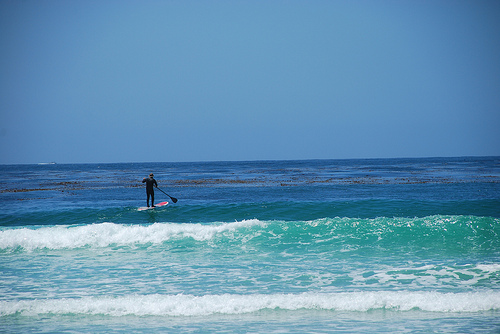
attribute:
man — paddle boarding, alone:
[141, 173, 157, 208]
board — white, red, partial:
[139, 198, 172, 218]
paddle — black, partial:
[152, 184, 181, 205]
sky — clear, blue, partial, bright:
[1, 1, 500, 163]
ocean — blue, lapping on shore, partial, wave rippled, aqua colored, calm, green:
[2, 156, 498, 333]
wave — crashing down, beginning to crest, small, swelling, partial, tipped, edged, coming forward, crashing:
[2, 207, 499, 315]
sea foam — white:
[3, 216, 267, 259]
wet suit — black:
[142, 176, 160, 209]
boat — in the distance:
[37, 160, 57, 168]